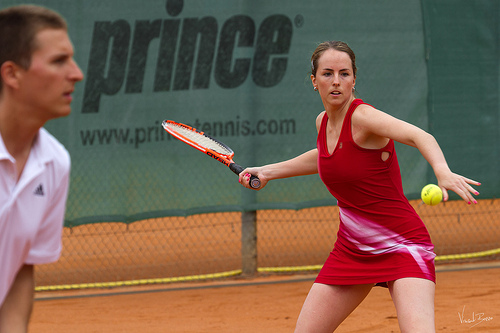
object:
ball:
[419, 183, 444, 206]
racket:
[161, 119, 262, 189]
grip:
[228, 162, 263, 190]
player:
[236, 39, 483, 333]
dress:
[312, 99, 436, 289]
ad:
[77, 0, 304, 150]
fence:
[0, 0, 500, 297]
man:
[0, 4, 83, 333]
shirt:
[0, 127, 73, 307]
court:
[0, 268, 500, 333]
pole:
[241, 211, 257, 279]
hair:
[311, 39, 357, 78]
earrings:
[312, 86, 319, 92]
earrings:
[351, 87, 357, 92]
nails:
[466, 201, 472, 204]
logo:
[34, 184, 45, 196]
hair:
[0, 4, 70, 72]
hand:
[237, 166, 269, 191]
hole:
[380, 151, 391, 162]